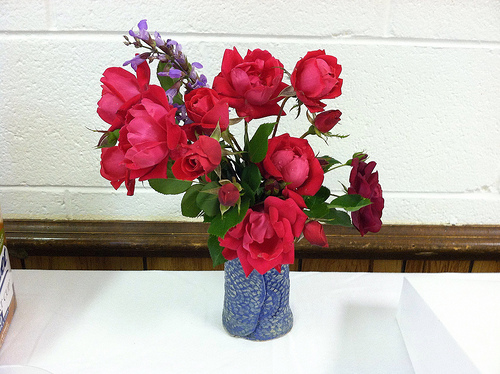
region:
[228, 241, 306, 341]
the vase is blue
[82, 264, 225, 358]
the table is white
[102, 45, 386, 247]
red roses in vase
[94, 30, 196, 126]
purple flowers in vase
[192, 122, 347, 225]
green leaves on flowers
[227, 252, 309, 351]
small vase on table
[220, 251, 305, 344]
vase is white and blue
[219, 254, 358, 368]
vase on white table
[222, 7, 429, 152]
white wall behind flowers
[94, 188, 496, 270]
brown ledge under wall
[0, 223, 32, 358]
bottle to left of vase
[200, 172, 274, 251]
small and unbloomed flower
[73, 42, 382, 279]
the flowers are red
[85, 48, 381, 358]
flowers in blue vase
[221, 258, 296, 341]
blue and beige painted ceramic vase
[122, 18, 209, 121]
small light purple flowers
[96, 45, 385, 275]
large group of red roses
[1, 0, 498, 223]
white painted concrete block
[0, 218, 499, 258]
wood trim along white wall and wood paneling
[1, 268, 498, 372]
large white table with vase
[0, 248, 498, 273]
brown wood textured paneling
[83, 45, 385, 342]
bunch of red roses in blue vase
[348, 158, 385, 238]
large dark red rose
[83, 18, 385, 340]
large bunch of flowers in blue vase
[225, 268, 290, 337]
a vase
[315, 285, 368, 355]
a table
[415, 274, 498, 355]
the box is white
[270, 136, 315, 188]
the flower is red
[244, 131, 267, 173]
a green leaf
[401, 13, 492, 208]
the wall is white and made of bricks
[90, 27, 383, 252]
flowers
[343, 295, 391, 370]
a shadow on the table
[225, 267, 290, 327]
the vase is blue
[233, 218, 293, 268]
flower is red